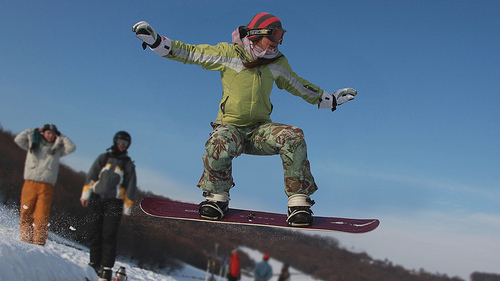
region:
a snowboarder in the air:
[112, 4, 462, 274]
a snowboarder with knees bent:
[119, 4, 442, 267]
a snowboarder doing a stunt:
[112, 0, 447, 267]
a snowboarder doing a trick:
[97, 0, 464, 277]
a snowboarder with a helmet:
[116, 0, 414, 272]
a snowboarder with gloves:
[97, 2, 453, 250]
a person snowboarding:
[114, 4, 432, 275]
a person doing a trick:
[112, 9, 437, 264]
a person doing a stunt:
[107, 11, 411, 278]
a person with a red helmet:
[122, 5, 415, 275]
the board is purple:
[141, 195, 379, 240]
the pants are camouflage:
[197, 125, 322, 194]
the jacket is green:
[182, 44, 321, 115]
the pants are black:
[88, 199, 120, 263]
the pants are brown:
[17, 182, 52, 235]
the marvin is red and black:
[247, 13, 293, 32]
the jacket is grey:
[17, 128, 82, 177]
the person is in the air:
[135, 22, 362, 217]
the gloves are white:
[318, 83, 359, 110]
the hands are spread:
[130, 11, 362, 223]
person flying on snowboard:
[99, 3, 401, 245]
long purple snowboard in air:
[99, 190, 376, 240]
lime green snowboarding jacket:
[150, 42, 317, 131]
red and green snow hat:
[242, 13, 280, 37]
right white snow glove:
[124, 17, 161, 44]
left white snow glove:
[329, 80, 362, 113]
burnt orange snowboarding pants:
[0, 170, 47, 246]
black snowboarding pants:
[82, 201, 113, 263]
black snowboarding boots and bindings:
[181, 186, 312, 221]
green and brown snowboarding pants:
[186, 120, 317, 193]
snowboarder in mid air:
[124, 2, 449, 242]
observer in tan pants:
[22, 112, 76, 259]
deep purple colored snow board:
[154, 186, 426, 248]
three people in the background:
[207, 238, 319, 279]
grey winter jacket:
[20, 131, 72, 176]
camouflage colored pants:
[193, 125, 381, 192]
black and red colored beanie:
[245, 2, 305, 68]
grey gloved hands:
[124, 18, 219, 80]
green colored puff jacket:
[191, 19, 341, 156]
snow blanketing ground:
[22, 250, 85, 278]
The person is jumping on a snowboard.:
[118, 5, 419, 248]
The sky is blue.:
[22, 18, 107, 63]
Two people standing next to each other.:
[6, 105, 134, 275]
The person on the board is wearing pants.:
[181, 105, 331, 210]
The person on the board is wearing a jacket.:
[163, 36, 330, 141]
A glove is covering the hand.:
[120, 10, 180, 65]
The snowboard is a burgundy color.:
[121, 188, 391, 258]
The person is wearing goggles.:
[240, 23, 290, 46]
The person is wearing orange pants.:
[11, 175, 52, 252]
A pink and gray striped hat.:
[243, 6, 285, 33]